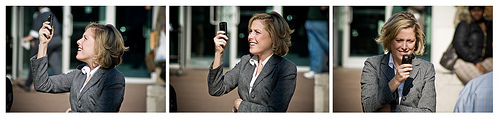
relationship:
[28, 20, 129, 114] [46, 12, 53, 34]
woman lifting phone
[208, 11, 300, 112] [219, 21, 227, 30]
woman looking at phone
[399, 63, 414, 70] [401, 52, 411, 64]
finger wrapped around phone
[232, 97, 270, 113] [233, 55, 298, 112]
arm around body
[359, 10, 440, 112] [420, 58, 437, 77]
woman has shoulder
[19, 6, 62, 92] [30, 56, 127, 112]
person wearing suit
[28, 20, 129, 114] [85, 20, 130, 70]
woman has hair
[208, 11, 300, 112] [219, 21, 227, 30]
woman holding phone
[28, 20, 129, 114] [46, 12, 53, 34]
woman holding phone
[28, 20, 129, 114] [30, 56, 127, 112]
woman wearing suit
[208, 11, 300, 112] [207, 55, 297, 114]
woman wearing suit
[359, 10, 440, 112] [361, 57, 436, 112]
woman wearing suit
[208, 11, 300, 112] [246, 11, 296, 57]
woman with hair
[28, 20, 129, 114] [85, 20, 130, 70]
woman with hair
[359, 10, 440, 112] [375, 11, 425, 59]
woman has hair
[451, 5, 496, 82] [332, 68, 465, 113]
person on sidewalk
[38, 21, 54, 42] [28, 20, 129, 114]
hand of woman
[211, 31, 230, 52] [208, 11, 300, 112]
hand of woman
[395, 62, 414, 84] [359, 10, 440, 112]
hand of woman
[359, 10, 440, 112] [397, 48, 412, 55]
woman has smile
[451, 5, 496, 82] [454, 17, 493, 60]
person wearing jacket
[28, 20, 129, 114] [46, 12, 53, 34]
woman looking up at phone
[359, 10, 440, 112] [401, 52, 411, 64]
woman looking down at phone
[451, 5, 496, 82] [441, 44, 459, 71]
person has bag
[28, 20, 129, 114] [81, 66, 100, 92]
woman wearing shirt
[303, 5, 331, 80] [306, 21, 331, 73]
person wearing jeans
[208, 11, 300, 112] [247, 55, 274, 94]
woman wearing shirt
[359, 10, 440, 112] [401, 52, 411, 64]
woman using phone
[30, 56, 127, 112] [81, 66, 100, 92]
suit over shirt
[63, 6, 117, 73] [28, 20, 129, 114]
door behind woman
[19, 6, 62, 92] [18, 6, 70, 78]
person walking through door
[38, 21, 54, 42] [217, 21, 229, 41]
hand holding phone